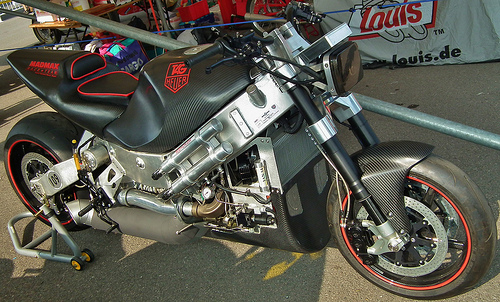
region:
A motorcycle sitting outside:
[3, 34, 485, 296]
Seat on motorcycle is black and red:
[8, 45, 140, 126]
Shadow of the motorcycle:
[3, 222, 338, 299]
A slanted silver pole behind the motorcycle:
[18, 1, 499, 151]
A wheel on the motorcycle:
[329, 154, 486, 294]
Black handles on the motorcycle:
[177, 18, 332, 69]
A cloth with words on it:
[311, 2, 496, 74]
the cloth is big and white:
[313, 3, 494, 77]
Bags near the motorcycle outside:
[87, 40, 147, 70]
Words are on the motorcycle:
[11, 55, 222, 123]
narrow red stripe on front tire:
[335, 169, 472, 290]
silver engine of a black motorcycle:
[69, 94, 345, 248]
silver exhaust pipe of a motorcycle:
[52, 190, 209, 250]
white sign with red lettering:
[338, 2, 438, 40]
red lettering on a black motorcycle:
[157, 58, 199, 98]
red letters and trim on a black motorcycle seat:
[0, 40, 145, 130]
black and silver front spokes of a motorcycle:
[279, 45, 425, 253]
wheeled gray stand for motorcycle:
[3, 192, 103, 270]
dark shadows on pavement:
[102, 234, 355, 299]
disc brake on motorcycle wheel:
[348, 192, 453, 278]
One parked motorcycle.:
[2, 0, 498, 300]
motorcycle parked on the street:
[2, 6, 496, 294]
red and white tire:
[332, 146, 490, 300]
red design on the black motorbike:
[158, 57, 196, 96]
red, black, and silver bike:
[4, 19, 498, 299]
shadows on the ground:
[1, 226, 321, 299]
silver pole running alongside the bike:
[21, 3, 493, 153]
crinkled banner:
[314, 0, 497, 75]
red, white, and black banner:
[307, 1, 499, 76]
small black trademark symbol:
[433, 25, 447, 39]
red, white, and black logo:
[343, 2, 440, 44]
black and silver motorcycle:
[2, 18, 497, 298]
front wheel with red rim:
[324, 146, 496, 298]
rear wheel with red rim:
[1, 107, 93, 232]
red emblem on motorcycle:
[161, 57, 191, 93]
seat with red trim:
[66, 45, 141, 115]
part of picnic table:
[25, 7, 120, 46]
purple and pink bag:
[96, 37, 153, 74]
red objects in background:
[173, 0, 298, 22]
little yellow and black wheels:
[68, 248, 94, 270]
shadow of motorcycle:
[1, 225, 338, 298]